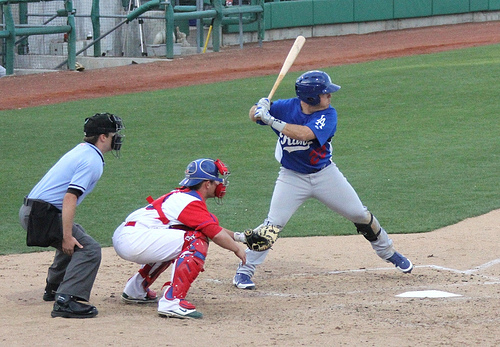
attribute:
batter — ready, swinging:
[233, 67, 412, 288]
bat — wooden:
[252, 34, 305, 116]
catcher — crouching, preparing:
[108, 155, 246, 318]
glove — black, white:
[242, 220, 282, 254]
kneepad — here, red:
[173, 231, 209, 291]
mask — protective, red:
[211, 157, 231, 201]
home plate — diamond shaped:
[394, 285, 459, 302]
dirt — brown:
[2, 204, 496, 347]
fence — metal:
[1, 3, 263, 69]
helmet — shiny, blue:
[295, 70, 341, 104]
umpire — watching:
[51, 294, 98, 318]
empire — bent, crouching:
[18, 112, 124, 323]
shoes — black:
[42, 285, 98, 320]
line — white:
[252, 257, 498, 307]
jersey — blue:
[258, 97, 338, 175]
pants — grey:
[245, 164, 392, 276]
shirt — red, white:
[127, 191, 227, 239]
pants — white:
[110, 221, 190, 260]